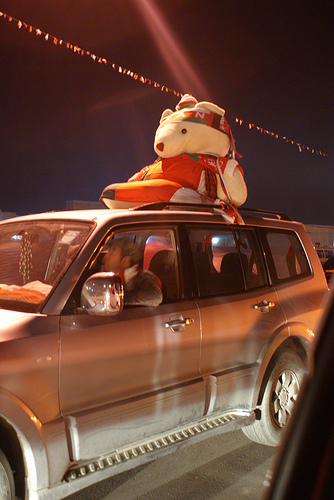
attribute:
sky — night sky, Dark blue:
[3, 2, 331, 189]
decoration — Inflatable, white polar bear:
[101, 94, 253, 208]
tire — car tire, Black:
[239, 343, 309, 447]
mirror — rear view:
[86, 263, 139, 322]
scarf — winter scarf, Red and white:
[113, 263, 162, 288]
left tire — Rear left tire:
[241, 339, 316, 456]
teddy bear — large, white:
[126, 93, 248, 207]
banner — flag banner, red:
[3, 9, 331, 155]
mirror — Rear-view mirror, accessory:
[60, 262, 133, 330]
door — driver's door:
[61, 220, 205, 484]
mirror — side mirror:
[79, 270, 123, 317]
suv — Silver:
[0, 209, 331, 498]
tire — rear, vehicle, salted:
[241, 348, 305, 445]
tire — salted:
[1, 454, 22, 498]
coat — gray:
[120, 267, 164, 311]